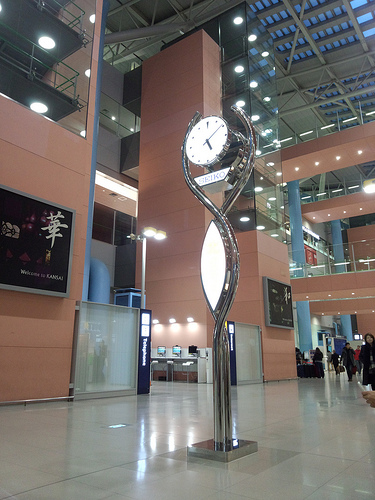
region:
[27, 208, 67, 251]
Asian writing on wall picture.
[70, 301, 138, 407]
See thru gray screen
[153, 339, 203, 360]
Computers on a table.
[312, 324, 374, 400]
A group of people walking.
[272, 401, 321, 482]
Tan and white tile floor.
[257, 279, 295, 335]
Black and gray wall art.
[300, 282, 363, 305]
Three white lights.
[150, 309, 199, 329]
Three white lights with shadows.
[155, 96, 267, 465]
Tall silver and white clock.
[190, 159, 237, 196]
Silver word that says seiko.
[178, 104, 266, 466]
Modern art structure for clock.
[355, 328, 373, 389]
Woman dressed in black walking in mall.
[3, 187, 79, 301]
Black sign trimmed in gray hanging on wall.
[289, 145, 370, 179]
Lights embedded in ceiling of mall.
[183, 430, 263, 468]
Base of clock art structure.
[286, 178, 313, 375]
Blue ceiling to floor support beam.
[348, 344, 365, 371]
Person dressed in red top walking in mall.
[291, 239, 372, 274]
Glass safety rail on second floor.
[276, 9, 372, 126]
Metal girders in ceiling.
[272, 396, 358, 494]
A shiny tiled floor.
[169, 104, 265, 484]
decorative clock tower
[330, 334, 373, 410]
people walking thru building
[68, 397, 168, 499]
shiny white tile floor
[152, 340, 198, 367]
computer monitors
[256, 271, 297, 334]
advertising board attached to wall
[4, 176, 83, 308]
advertising board attached to wall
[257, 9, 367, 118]
skylight on ceiling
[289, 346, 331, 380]
people waiting in line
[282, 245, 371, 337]
second floor walk way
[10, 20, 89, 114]
safety railing on second floor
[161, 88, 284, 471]
Floor clock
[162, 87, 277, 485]
Floor clock has ornaments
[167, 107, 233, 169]
Clock is white with steel frame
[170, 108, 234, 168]
Clock has cardinal numbers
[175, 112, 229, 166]
Clock displays 5:10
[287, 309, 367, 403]
People walk in a hallway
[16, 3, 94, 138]
Lights in a building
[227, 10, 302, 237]
Lights in a building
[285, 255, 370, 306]
Bridge with rails is orange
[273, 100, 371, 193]
Lights below the bridge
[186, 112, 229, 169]
Clock on top of the metal bars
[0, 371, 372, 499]
The tile floors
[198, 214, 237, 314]
The light in the middle of the clock sculpture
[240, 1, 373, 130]
The sun lights on the roof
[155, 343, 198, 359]
The computers lined on the wall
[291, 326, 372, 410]
The people shown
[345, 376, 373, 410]
The disembodied hand holding the phone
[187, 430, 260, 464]
The base of the clock sculpture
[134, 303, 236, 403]
Two blue towers with lights next to computers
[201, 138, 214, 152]
The hour hand on the clock